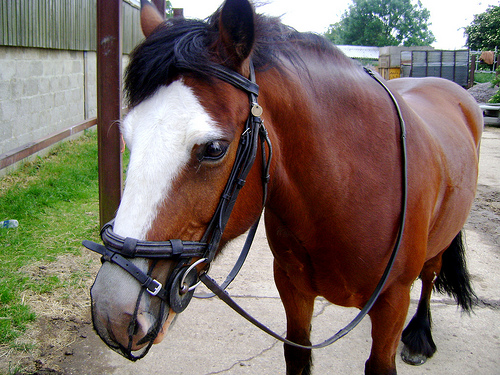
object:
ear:
[215, 0, 257, 79]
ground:
[2, 227, 91, 375]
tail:
[430, 226, 480, 319]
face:
[90, 19, 262, 349]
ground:
[162, 315, 244, 375]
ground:
[447, 309, 499, 375]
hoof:
[400, 303, 436, 367]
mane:
[122, 17, 306, 89]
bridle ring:
[179, 257, 213, 291]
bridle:
[81, 12, 267, 364]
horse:
[85, 0, 485, 375]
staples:
[180, 332, 232, 374]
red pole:
[92, 2, 121, 233]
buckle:
[147, 279, 164, 296]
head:
[89, 0, 276, 357]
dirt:
[463, 82, 498, 103]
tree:
[324, 2, 432, 47]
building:
[333, 42, 383, 58]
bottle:
[1, 218, 19, 227]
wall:
[0, 1, 154, 169]